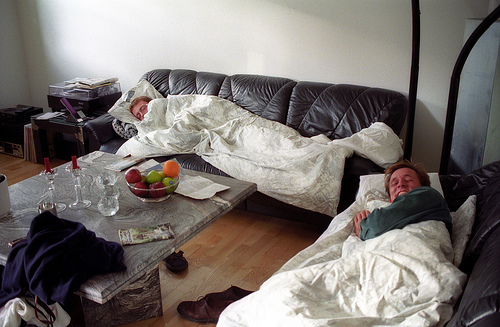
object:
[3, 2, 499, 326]
room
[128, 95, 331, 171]
man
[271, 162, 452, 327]
man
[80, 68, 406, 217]
couch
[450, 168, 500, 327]
couch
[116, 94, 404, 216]
blanket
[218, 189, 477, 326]
blanket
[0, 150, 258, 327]
coffee table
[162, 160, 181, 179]
fruit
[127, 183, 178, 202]
bowl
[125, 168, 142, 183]
apple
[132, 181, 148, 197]
apple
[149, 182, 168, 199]
apple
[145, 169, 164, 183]
apple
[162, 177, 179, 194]
apple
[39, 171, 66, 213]
candlestick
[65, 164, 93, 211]
candlestick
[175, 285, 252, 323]
shoes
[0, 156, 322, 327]
floor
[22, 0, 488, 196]
walls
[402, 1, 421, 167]
railings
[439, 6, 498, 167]
railings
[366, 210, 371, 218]
fingers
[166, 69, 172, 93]
lines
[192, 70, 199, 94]
lines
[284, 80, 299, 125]
lines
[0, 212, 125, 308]
clothing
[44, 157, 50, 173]
candle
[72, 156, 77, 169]
candle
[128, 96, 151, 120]
head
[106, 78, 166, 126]
pillow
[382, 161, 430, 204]
head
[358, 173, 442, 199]
pillow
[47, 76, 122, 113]
record player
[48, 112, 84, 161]
table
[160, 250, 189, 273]
sandal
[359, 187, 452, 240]
shirt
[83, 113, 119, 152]
arms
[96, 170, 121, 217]
glassware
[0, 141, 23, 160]
stereo system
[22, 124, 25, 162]
records